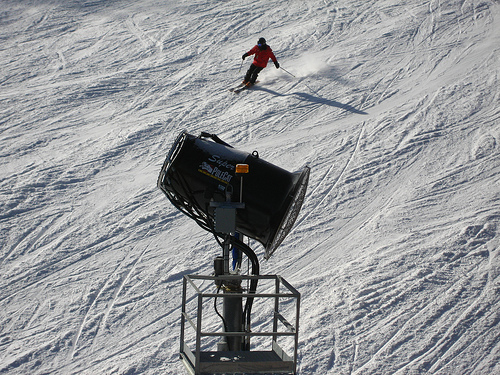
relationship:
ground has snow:
[33, 29, 79, 335] [96, 29, 141, 333]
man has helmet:
[225, 36, 281, 97] [257, 35, 267, 50]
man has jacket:
[225, 36, 281, 97] [249, 49, 276, 66]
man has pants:
[225, 36, 281, 97] [245, 64, 264, 82]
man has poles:
[225, 36, 281, 97] [237, 59, 300, 79]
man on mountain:
[225, 36, 281, 97] [41, 14, 427, 121]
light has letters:
[163, 136, 316, 258] [200, 151, 239, 194]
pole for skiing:
[282, 64, 300, 85] [209, 67, 302, 100]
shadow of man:
[258, 78, 370, 115] [225, 36, 281, 97]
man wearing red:
[225, 36, 281, 97] [260, 52, 267, 60]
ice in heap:
[64, 58, 144, 115] [31, 19, 163, 170]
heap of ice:
[31, 19, 163, 170] [64, 58, 144, 115]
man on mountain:
[240, 37, 280, 89] [41, 14, 427, 121]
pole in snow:
[282, 64, 300, 85] [270, 85, 342, 114]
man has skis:
[225, 36, 281, 97] [228, 81, 262, 93]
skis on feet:
[228, 81, 262, 93] [243, 78, 252, 89]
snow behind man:
[287, 45, 326, 81] [225, 36, 281, 97]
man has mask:
[225, 36, 281, 97] [254, 41, 268, 46]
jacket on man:
[249, 49, 276, 66] [240, 37, 280, 89]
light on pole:
[235, 159, 248, 177] [237, 179, 244, 203]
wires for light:
[159, 168, 222, 250] [163, 136, 316, 258]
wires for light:
[159, 162, 259, 352] [163, 136, 316, 258]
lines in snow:
[349, 270, 417, 328] [310, 169, 469, 368]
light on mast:
[163, 136, 316, 258] [202, 237, 263, 358]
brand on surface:
[200, 167, 234, 181] [194, 144, 239, 204]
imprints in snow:
[380, 8, 468, 39] [349, 12, 481, 120]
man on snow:
[240, 37, 280, 89] [96, 29, 141, 333]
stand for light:
[155, 208, 310, 372] [163, 136, 316, 258]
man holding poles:
[225, 36, 281, 97] [237, 59, 300, 79]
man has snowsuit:
[225, 36, 281, 97] [245, 43, 266, 89]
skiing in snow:
[209, 67, 302, 100] [96, 29, 141, 333]